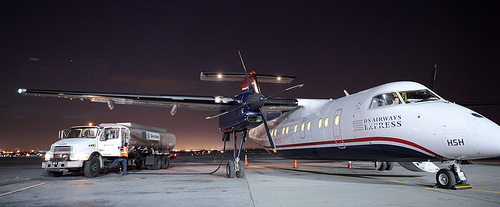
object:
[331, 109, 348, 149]
closed door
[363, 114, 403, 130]
airline's name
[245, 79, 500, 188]
side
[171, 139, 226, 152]
glow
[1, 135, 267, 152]
horizon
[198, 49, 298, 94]
blade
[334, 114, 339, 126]
window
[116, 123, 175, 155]
tank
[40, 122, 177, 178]
truck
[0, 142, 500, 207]
tarmac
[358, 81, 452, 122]
cockpit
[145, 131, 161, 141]
sign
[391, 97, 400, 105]
pilot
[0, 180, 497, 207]
asphalt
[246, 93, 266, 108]
core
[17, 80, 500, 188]
plane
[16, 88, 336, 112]
wing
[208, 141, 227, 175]
fuel line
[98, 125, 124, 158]
door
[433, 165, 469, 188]
gear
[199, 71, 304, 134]
jet engine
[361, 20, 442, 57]
sky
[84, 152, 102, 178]
tire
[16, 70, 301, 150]
propeller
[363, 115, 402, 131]
logo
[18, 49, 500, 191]
airplain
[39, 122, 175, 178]
tanker truck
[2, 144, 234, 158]
lights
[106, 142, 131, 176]
person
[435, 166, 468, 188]
wheel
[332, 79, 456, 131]
cabin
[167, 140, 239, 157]
city